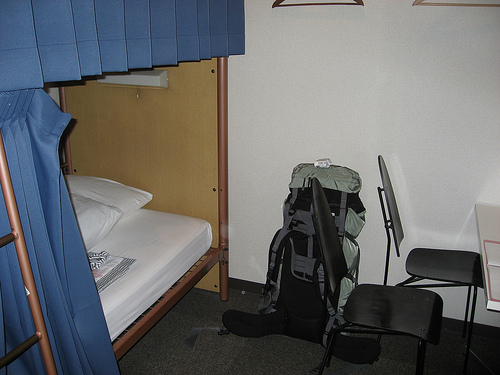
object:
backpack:
[222, 158, 368, 349]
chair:
[313, 283, 443, 375]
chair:
[376, 153, 486, 365]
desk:
[475, 202, 500, 312]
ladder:
[0, 99, 63, 375]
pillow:
[63, 173, 156, 217]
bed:
[77, 210, 215, 343]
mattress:
[86, 208, 215, 342]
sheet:
[86, 208, 213, 343]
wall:
[227, 0, 499, 329]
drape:
[1, 88, 119, 374]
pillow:
[69, 194, 123, 251]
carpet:
[110, 282, 498, 374]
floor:
[118, 290, 500, 375]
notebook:
[482, 238, 500, 303]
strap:
[259, 226, 292, 314]